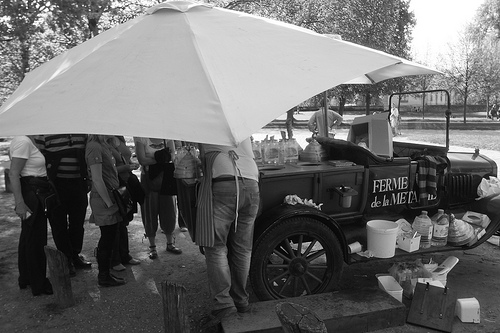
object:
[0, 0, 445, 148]
umbrella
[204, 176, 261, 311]
jeans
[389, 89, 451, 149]
dark frame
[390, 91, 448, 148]
windscreen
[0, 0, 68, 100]
tree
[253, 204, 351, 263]
front fender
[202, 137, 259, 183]
shirt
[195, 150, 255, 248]
apron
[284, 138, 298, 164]
bottles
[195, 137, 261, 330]
person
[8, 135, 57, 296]
person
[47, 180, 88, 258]
dark pants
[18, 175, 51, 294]
dark pants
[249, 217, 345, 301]
wheel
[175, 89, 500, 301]
car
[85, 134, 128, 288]
person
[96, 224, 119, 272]
pants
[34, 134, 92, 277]
people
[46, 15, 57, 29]
leaves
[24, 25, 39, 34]
leaves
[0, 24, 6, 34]
leaves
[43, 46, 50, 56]
leaves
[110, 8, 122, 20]
leaves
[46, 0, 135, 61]
tree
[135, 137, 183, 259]
person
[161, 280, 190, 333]
post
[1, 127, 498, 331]
ground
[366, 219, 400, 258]
bucket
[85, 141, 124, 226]
dress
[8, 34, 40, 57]
leaves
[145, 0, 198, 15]
top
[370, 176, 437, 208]
name